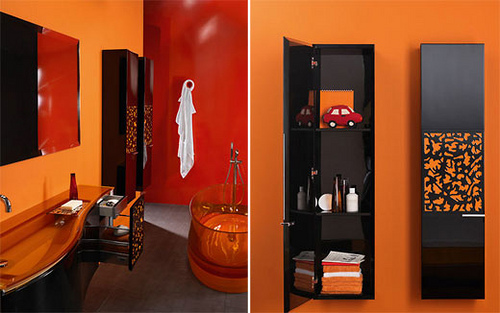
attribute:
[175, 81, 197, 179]
towel — white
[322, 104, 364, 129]
toy — red, small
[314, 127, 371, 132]
shelf — black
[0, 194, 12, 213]
faucet — chrome, silver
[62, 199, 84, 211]
soap — white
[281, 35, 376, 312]
cabinet — black, open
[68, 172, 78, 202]
bottle — red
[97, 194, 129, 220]
drawer — open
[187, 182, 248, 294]
tub — modern, orange, glass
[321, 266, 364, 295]
washcloths — orange, stacked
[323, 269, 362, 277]
towel — white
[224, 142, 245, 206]
faucet — silver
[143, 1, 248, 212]
wall — red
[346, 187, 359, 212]
bottle — white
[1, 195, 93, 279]
sink — silver, orange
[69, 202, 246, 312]
floor — gray